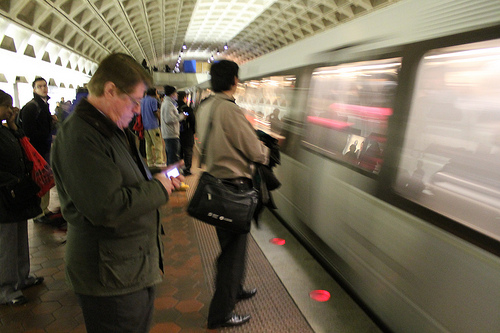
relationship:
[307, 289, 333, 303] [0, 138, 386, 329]
light on ground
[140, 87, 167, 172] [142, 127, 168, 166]
man wearing pants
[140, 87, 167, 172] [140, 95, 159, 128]
man wearing shirt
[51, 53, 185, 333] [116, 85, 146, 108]
man wearing glasses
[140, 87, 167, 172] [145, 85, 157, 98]
man has head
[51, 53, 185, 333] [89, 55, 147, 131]
man has head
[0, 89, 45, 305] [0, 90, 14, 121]
woman has head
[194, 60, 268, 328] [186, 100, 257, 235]
man carrying shoulder bag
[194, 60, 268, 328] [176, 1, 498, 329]
man near train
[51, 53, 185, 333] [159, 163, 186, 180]
man looking at cellphone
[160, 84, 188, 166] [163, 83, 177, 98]
person wearing hat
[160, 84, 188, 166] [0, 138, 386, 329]
person standing on ground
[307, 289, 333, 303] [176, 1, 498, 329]
light near train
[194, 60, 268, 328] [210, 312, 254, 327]
man wearing shoe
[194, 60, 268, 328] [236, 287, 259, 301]
man wearing shoe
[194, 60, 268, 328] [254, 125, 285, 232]
man holding coat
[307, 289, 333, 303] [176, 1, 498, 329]
light under train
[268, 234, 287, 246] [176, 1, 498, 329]
light under train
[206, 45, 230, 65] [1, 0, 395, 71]
lights on ceiling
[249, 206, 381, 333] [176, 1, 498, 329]
stripe next to train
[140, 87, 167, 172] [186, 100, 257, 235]
man carrying shoulder bag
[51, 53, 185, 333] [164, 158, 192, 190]
man has left hand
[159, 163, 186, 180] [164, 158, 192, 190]
cellphone in left hand